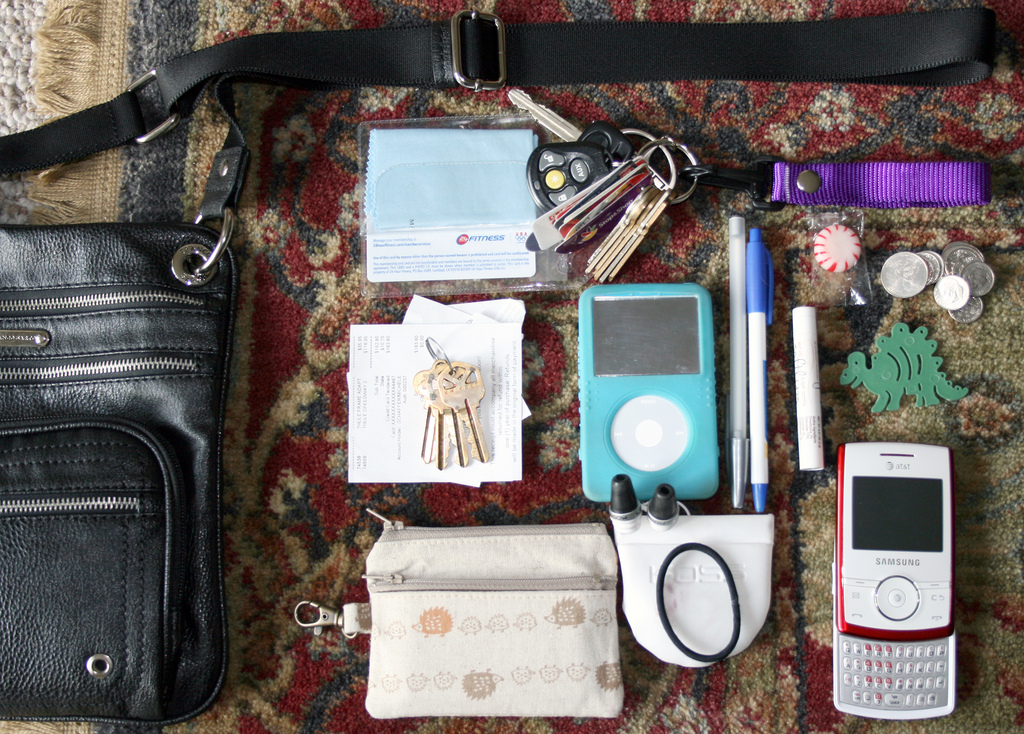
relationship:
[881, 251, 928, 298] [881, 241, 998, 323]
coin lying in collection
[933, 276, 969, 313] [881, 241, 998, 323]
coin lying in collection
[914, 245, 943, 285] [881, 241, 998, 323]
coin lying in collection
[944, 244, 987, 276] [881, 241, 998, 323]
coin lying in collection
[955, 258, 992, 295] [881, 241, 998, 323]
coin lying in collection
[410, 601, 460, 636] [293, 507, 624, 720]
porcupine printed on item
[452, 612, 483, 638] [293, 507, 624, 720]
porcupine printed on item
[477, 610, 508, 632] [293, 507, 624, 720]
porcupine printed on item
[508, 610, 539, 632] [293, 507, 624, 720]
porcupine printed on item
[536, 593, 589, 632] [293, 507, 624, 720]
porcupine printed on item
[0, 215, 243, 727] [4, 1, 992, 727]
purse belonging to crossbody bag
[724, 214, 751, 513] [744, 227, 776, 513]
pen lying next to ballpoint pen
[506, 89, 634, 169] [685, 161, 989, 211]
key attached to item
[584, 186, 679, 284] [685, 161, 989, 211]
key attached to item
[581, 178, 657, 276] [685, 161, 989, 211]
key attached to item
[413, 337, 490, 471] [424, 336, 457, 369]
set attached to keyring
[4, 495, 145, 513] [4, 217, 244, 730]
zipper stitched on purse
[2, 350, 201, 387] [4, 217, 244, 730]
zipper stitched on purse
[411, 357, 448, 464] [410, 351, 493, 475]
car key hanging in set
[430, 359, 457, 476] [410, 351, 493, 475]
car key hanging in set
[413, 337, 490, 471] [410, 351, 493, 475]
set hanging in set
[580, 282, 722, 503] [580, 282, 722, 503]
ipod covering ipod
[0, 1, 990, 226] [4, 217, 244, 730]
strap attached to purse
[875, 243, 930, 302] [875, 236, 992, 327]
coin lying in collection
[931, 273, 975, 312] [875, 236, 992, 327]
coin lying in collection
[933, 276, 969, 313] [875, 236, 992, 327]
coin lying in collection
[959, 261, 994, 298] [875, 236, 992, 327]
coin lying in collection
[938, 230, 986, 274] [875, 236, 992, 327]
coin lying in collection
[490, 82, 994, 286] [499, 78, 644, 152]
key ring has key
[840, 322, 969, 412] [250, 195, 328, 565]
item on rug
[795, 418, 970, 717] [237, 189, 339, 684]
item on rug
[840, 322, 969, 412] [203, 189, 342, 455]
item on rug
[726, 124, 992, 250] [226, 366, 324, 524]
item on rug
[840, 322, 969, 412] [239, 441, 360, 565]
item on rug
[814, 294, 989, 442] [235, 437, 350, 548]
item on rug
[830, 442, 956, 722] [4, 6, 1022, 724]
item on rug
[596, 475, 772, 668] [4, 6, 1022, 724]
item on rug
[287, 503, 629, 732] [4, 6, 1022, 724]
item on rug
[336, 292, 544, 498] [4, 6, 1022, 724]
item on rug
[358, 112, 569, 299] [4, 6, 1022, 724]
lanyard on rug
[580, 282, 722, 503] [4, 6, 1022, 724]
ipod on rug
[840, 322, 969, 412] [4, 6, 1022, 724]
item on rug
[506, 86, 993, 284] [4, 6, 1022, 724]
key ring on rug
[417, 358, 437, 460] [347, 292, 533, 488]
key on item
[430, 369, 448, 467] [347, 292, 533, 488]
key on item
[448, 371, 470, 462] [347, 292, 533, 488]
key on item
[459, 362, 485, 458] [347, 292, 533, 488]
key on item